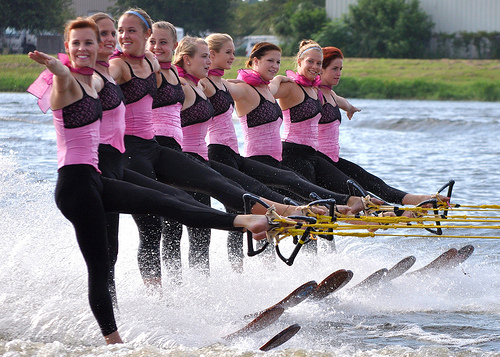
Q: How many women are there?
A: Nine.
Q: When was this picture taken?
A: Daytime.